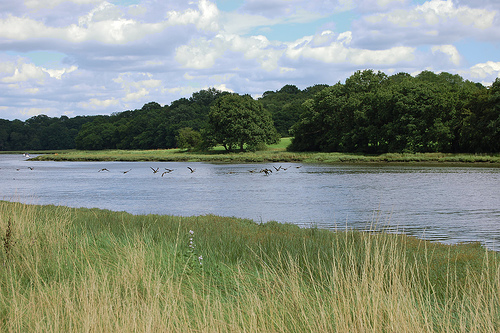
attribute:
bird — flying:
[255, 157, 281, 185]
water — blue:
[338, 188, 441, 229]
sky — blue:
[181, 9, 278, 50]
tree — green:
[209, 86, 269, 133]